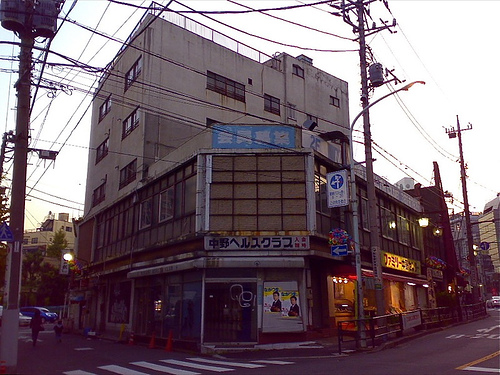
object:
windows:
[263, 92, 281, 117]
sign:
[211, 124, 296, 149]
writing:
[216, 130, 291, 147]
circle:
[329, 174, 344, 190]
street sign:
[325, 169, 349, 209]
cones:
[163, 329, 176, 353]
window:
[173, 171, 197, 220]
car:
[486, 295, 500, 308]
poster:
[263, 286, 303, 320]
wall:
[256, 267, 307, 332]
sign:
[330, 244, 349, 257]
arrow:
[333, 247, 346, 255]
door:
[204, 284, 243, 341]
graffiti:
[228, 283, 254, 308]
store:
[323, 268, 389, 337]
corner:
[311, 265, 332, 329]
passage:
[319, 299, 490, 354]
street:
[382, 312, 498, 375]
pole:
[349, 160, 369, 348]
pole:
[354, 0, 388, 317]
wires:
[396, 22, 459, 121]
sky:
[0, 0, 500, 230]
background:
[0, 0, 500, 221]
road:
[7, 315, 201, 375]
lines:
[159, 359, 236, 374]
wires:
[30, 139, 318, 183]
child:
[52, 319, 65, 345]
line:
[454, 351, 499, 371]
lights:
[435, 229, 440, 233]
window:
[261, 280, 302, 333]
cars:
[14, 313, 43, 326]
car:
[21, 306, 59, 323]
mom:
[29, 308, 45, 350]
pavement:
[10, 349, 295, 375]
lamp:
[418, 217, 430, 228]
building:
[66, 12, 354, 347]